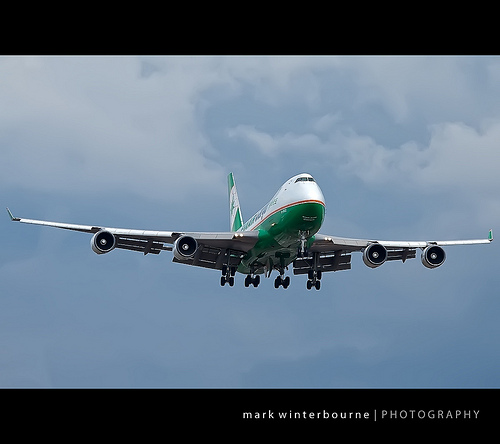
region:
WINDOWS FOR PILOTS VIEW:
[286, 158, 324, 192]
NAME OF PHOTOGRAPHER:
[226, 399, 376, 423]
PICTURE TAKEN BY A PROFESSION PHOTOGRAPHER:
[243, 358, 494, 429]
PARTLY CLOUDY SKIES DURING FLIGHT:
[26, 157, 151, 231]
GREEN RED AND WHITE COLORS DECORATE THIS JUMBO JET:
[275, 166, 336, 246]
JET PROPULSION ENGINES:
[355, 228, 455, 277]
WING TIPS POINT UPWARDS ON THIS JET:
[4, 198, 66, 243]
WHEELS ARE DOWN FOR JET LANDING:
[206, 252, 328, 309]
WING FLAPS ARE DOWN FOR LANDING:
[98, 214, 178, 264]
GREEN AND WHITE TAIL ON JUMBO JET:
[206, 150, 248, 235]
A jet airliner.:
[18, 91, 488, 306]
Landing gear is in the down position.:
[210, 247, 330, 307]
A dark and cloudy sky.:
[65, 71, 435, 206]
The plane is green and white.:
[200, 132, 336, 312]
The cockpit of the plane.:
[287, 166, 317, 191]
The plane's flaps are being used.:
[97, 220, 437, 295]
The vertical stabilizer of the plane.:
[211, 160, 251, 241]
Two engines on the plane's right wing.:
[10, 200, 241, 290]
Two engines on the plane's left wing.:
[330, 206, 485, 316]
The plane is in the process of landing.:
[20, 103, 485, 331]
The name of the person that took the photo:
[240, 405, 483, 423]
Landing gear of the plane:
[215, 250, 322, 295]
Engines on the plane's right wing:
[84, 226, 199, 262]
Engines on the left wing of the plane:
[360, 242, 447, 270]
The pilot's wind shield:
[293, 175, 316, 185]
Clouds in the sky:
[2, 56, 497, 205]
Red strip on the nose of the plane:
[280, 198, 326, 211]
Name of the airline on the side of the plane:
[233, 204, 270, 231]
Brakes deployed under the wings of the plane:
[106, 235, 420, 275]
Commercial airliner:
[4, 168, 496, 295]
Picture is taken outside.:
[18, 156, 478, 384]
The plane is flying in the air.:
[16, 150, 480, 333]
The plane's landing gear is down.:
[214, 240, 357, 308]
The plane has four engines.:
[73, 190, 443, 279]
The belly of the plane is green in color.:
[255, 223, 337, 254]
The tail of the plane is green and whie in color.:
[225, 173, 244, 230]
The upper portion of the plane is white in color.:
[242, 170, 326, 195]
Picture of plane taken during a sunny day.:
[25, 148, 492, 274]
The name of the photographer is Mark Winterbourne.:
[237, 378, 483, 438]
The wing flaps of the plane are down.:
[114, 228, 424, 283]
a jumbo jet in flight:
[6, 163, 493, 296]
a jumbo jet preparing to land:
[1, 162, 491, 297]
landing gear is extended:
[203, 256, 340, 299]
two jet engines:
[356, 228, 446, 274]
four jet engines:
[86, 230, 456, 270]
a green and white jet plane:
[5, 162, 493, 294]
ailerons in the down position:
[56, 220, 458, 276]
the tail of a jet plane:
[208, 161, 253, 266]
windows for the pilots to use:
[286, 161, 327, 188]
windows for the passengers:
[236, 193, 282, 233]